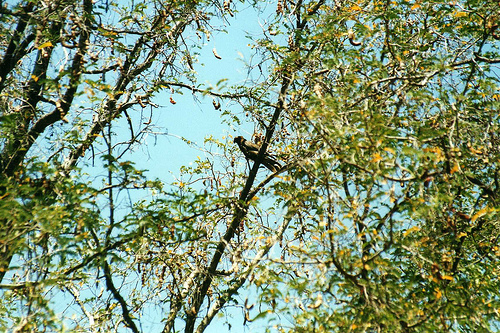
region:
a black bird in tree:
[230, 131, 277, 171]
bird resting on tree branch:
[231, 134, 281, 171]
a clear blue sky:
[0, 0, 498, 331]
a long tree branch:
[182, 2, 310, 330]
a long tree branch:
[1, 0, 96, 184]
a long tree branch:
[1, 22, 58, 159]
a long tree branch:
[2, 0, 34, 82]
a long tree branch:
[351, 53, 498, 110]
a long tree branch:
[293, 96, 498, 206]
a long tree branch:
[438, 188, 484, 290]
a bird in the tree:
[197, 86, 439, 278]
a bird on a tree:
[164, 53, 390, 294]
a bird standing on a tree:
[199, 39, 411, 329]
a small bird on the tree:
[132, 12, 421, 317]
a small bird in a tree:
[157, 33, 436, 283]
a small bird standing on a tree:
[148, 69, 496, 314]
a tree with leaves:
[14, 52, 471, 332]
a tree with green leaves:
[29, 25, 417, 332]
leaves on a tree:
[37, 43, 484, 275]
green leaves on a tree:
[32, 36, 461, 328]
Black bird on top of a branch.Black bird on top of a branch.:
[15, 11, 55, 28]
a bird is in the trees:
[182, 75, 389, 281]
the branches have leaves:
[32, 171, 180, 271]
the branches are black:
[202, 168, 322, 259]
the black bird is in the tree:
[217, 126, 360, 196]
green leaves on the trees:
[64, 175, 163, 260]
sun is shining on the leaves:
[223, 240, 362, 325]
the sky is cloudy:
[140, 113, 201, 163]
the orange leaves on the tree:
[273, 61, 388, 161]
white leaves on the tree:
[175, 215, 346, 306]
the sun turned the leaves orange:
[42, 154, 173, 300]